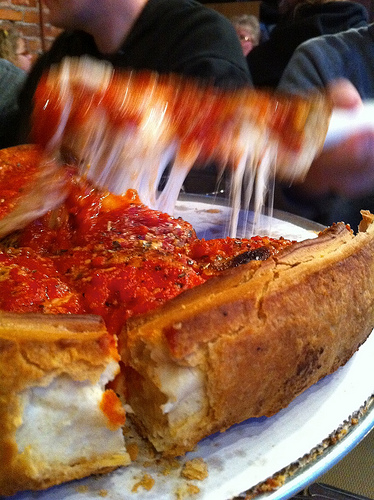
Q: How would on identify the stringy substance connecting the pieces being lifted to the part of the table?
A: Cheese.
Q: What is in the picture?
A: A deep dish pizza.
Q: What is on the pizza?
A: Red sauce.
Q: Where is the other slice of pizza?
A: In the air.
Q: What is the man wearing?
A: Black sweater.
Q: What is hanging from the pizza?
A: Cheese.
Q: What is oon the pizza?
A: Toamto sause.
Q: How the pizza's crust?
A: Thick.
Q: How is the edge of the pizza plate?
A: White.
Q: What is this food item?
A: Pizza.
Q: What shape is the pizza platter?
A: Circle.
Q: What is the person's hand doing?
A: Pulling a slice of pizza.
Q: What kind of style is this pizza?
A: Deep dish.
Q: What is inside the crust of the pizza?
A: Cheese.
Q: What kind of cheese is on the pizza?
A: Mozzerela.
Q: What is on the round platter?
A: Pizza.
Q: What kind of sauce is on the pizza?
A: Tomato.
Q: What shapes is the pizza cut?
A: Triangle.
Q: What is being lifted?
A: A slice of pizza.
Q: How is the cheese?
A: Melty.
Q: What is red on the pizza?
A: The sauce on the pizza.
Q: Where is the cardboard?
A: Under the pizza.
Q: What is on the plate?
A: Food.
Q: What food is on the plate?
A: Pizza.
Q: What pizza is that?
A: Deep Dish.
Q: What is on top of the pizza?
A: Sauce.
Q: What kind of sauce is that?
A: Tomato.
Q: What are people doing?
A: Eating.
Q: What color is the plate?
A: White.